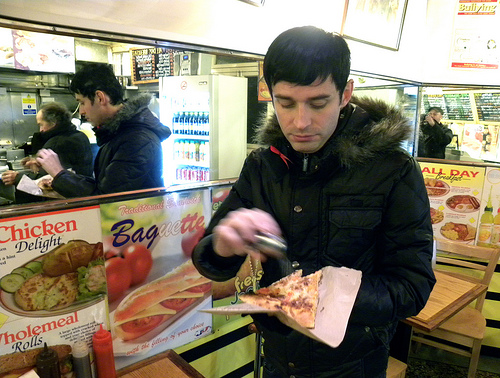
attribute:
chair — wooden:
[432, 237, 498, 377]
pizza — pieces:
[16, 155, 57, 195]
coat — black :
[229, 117, 424, 304]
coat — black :
[187, 94, 435, 376]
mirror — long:
[48, 47, 239, 214]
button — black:
[289, 201, 303, 218]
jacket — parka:
[190, 87, 440, 375]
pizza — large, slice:
[252, 260, 363, 362]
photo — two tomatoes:
[90, 246, 157, 299]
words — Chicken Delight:
[0, 216, 83, 256]